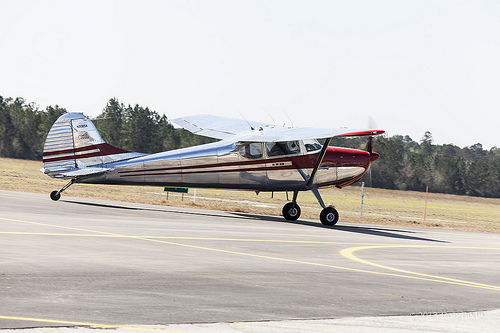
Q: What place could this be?
A: It is a runway.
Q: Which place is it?
A: It is a runway.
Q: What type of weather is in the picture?
A: It is cloudy.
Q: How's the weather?
A: It is cloudy.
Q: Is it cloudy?
A: Yes, it is cloudy.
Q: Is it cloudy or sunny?
A: It is cloudy.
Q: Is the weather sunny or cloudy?
A: It is cloudy.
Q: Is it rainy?
A: No, it is cloudy.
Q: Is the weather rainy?
A: No, it is cloudy.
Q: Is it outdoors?
A: Yes, it is outdoors.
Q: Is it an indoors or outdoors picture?
A: It is outdoors.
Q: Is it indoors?
A: No, it is outdoors.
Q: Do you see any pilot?
A: No, there are no pilots.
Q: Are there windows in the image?
A: Yes, there is a window.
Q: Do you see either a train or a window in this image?
A: Yes, there is a window.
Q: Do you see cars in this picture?
A: No, there are no cars.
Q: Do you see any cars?
A: No, there are no cars.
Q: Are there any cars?
A: No, there are no cars.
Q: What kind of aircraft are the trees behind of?
A: The trees are behind the airplane.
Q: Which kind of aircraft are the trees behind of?
A: The trees are behind the airplane.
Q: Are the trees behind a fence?
A: No, the trees are behind an airplane.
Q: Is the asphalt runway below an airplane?
A: Yes, the runway is below an airplane.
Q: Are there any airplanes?
A: Yes, there is an airplane.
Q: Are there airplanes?
A: Yes, there is an airplane.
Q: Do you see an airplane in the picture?
A: Yes, there is an airplane.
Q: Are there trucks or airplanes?
A: Yes, there is an airplane.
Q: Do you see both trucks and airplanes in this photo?
A: No, there is an airplane but no trucks.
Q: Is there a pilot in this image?
A: No, there are no pilots.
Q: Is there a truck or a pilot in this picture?
A: No, there are no pilots or trucks.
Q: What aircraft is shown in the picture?
A: The aircraft is an airplane.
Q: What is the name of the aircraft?
A: The aircraft is an airplane.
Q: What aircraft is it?
A: The aircraft is an airplane.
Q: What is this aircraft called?
A: That is an airplane.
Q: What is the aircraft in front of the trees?
A: The aircraft is an airplane.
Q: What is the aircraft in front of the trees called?
A: The aircraft is an airplane.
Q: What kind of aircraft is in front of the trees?
A: The aircraft is an airplane.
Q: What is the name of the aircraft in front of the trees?
A: The aircraft is an airplane.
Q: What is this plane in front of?
A: The plane is in front of the trees.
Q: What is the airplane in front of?
A: The plane is in front of the trees.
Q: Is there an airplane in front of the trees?
A: Yes, there is an airplane in front of the trees.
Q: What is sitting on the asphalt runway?
A: The airplane is sitting on the runway.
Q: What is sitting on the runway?
A: The airplane is sitting on the runway.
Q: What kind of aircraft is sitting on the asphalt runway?
A: The aircraft is an airplane.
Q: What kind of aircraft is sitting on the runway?
A: The aircraft is an airplane.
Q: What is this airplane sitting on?
A: The airplane is sitting on the runway.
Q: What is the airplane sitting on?
A: The airplane is sitting on the runway.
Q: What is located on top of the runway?
A: The airplane is on top of the runway.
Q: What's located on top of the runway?
A: The airplane is on top of the runway.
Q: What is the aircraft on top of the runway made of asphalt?
A: The aircraft is an airplane.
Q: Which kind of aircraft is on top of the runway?
A: The aircraft is an airplane.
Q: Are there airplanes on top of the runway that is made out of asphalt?
A: Yes, there is an airplane on top of the runway.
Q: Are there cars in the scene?
A: No, there are no cars.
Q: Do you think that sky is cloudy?
A: Yes, the sky is cloudy.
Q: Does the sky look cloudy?
A: Yes, the sky is cloudy.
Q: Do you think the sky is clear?
A: No, the sky is cloudy.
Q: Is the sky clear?
A: No, the sky is cloudy.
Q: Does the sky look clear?
A: No, the sky is cloudy.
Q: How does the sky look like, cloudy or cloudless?
A: The sky is cloudy.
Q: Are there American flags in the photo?
A: No, there are no American flags.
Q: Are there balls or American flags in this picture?
A: No, there are no American flags or balls.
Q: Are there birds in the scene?
A: No, there are no birds.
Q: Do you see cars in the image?
A: No, there are no cars.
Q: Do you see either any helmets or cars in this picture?
A: No, there are no cars or helmets.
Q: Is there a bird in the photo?
A: No, there are no birds.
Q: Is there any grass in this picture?
A: Yes, there is grass.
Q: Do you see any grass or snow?
A: Yes, there is grass.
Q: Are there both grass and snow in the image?
A: No, there is grass but no snow.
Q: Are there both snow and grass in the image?
A: No, there is grass but no snow.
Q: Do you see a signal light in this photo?
A: No, there are no traffic lights.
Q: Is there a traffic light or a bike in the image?
A: No, there are no traffic lights or bikes.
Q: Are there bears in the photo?
A: No, there are no bears.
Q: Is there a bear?
A: No, there are no bears.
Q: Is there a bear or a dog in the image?
A: No, there are no bears or dogs.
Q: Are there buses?
A: No, there are no buses.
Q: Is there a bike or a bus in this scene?
A: No, there are no buses or bikes.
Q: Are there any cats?
A: No, there are no cats.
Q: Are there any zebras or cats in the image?
A: No, there are no cats or zebras.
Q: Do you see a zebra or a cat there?
A: No, there are no cats or zebras.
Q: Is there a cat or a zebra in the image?
A: No, there are no cats or zebras.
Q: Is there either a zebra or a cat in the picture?
A: No, there are no cats or zebras.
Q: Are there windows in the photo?
A: Yes, there is a window.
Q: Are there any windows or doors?
A: Yes, there is a window.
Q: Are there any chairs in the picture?
A: No, there are no chairs.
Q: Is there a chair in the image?
A: No, there are no chairs.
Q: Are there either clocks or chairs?
A: No, there are no chairs or clocks.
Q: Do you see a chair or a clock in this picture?
A: No, there are no chairs or clocks.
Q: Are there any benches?
A: No, there are no benches.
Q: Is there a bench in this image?
A: No, there are no benches.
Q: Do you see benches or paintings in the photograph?
A: No, there are no benches or paintings.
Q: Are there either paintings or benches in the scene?
A: No, there are no benches or paintings.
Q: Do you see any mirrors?
A: No, there are no mirrors.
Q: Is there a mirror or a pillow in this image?
A: No, there are no mirrors or pillows.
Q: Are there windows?
A: Yes, there is a window.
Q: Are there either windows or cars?
A: Yes, there is a window.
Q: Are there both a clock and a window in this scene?
A: No, there is a window but no clocks.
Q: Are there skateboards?
A: No, there are no skateboards.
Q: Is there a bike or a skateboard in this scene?
A: No, there are no skateboards or bikes.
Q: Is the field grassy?
A: Yes, the field is grassy.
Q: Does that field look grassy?
A: Yes, the field is grassy.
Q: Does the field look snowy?
A: No, the field is grassy.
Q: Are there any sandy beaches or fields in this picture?
A: No, there is a field but it is grassy.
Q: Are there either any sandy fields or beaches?
A: No, there is a field but it is grassy.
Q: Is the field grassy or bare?
A: The field is grassy.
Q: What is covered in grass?
A: The field is covered in grass.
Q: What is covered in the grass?
A: The field is covered in grass.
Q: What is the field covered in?
A: The field is covered in grass.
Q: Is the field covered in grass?
A: Yes, the field is covered in grass.